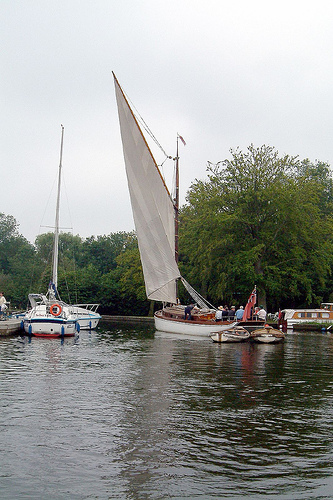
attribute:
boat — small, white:
[249, 323, 284, 342]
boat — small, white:
[209, 325, 249, 343]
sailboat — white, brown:
[82, 66, 219, 281]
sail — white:
[107, 88, 224, 274]